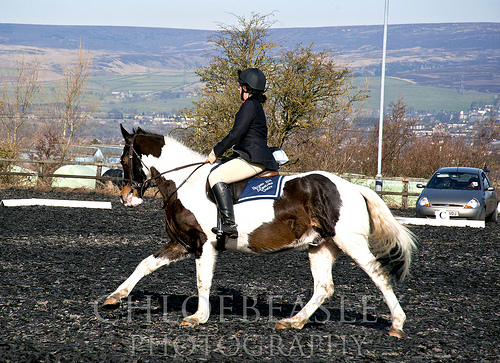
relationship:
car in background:
[419, 162, 495, 223] [20, 19, 143, 77]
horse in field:
[104, 123, 418, 362] [6, 245, 85, 350]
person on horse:
[205, 67, 277, 242] [104, 123, 418, 362]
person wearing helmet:
[205, 67, 277, 242] [229, 62, 270, 93]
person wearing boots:
[205, 67, 277, 242] [207, 188, 238, 235]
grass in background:
[119, 78, 159, 90] [20, 19, 143, 77]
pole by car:
[369, 2, 392, 188] [419, 162, 495, 223]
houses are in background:
[432, 101, 489, 132] [20, 19, 143, 77]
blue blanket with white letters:
[231, 173, 287, 198] [250, 176, 274, 193]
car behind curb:
[419, 162, 495, 223] [405, 214, 485, 231]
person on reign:
[205, 67, 277, 242] [160, 157, 223, 194]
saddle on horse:
[206, 173, 281, 202] [104, 123, 418, 362]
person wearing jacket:
[205, 67, 277, 242] [220, 98, 279, 165]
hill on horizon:
[410, 22, 500, 51] [4, 6, 499, 28]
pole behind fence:
[369, 2, 392, 188] [352, 176, 422, 194]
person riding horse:
[205, 67, 277, 242] [104, 123, 418, 362]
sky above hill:
[68, 6, 181, 28] [410, 22, 500, 51]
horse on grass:
[104, 123, 418, 362] [119, 78, 159, 90]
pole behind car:
[369, 2, 392, 188] [419, 162, 495, 223]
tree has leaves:
[279, 50, 339, 151] [287, 61, 311, 94]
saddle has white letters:
[206, 173, 281, 202] [250, 176, 274, 193]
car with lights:
[419, 162, 495, 223] [420, 196, 430, 206]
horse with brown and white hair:
[104, 123, 418, 362] [305, 174, 362, 232]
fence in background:
[352, 176, 422, 194] [20, 19, 143, 77]